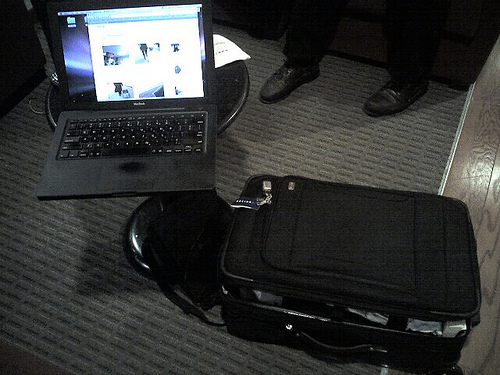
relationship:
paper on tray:
[216, 34, 245, 74] [44, 27, 251, 147]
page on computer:
[86, 8, 206, 102] [40, 3, 219, 200]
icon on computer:
[65, 12, 77, 28] [40, 3, 219, 200]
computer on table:
[40, 3, 219, 200] [211, 29, 259, 132]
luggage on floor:
[222, 167, 489, 370] [3, 21, 469, 371]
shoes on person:
[253, 56, 498, 191] [256, 3, 495, 253]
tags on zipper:
[231, 197, 261, 211] [252, 176, 276, 206]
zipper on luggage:
[257, 194, 273, 206] [147, 170, 481, 373]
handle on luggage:
[285, 326, 385, 365] [222, 167, 489, 370]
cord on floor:
[22, 92, 46, 118] [3, 21, 469, 371]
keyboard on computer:
[57, 109, 210, 161] [40, 3, 219, 200]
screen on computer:
[46, 4, 213, 109] [40, 3, 219, 200]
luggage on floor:
[222, 173, 480, 370] [3, 21, 469, 371]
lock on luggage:
[256, 177, 276, 210] [222, 173, 480, 370]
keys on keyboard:
[74, 112, 204, 152] [37, 105, 221, 195]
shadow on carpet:
[73, 134, 276, 300] [42, 31, 444, 373]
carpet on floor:
[0, 97, 454, 375] [460, 81, 499, 201]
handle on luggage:
[283, 323, 389, 365] [222, 173, 480, 370]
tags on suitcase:
[230, 177, 274, 211] [157, 148, 499, 357]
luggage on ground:
[222, 173, 480, 370] [8, 29, 485, 366]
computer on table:
[40, 3, 219, 200] [216, 49, 281, 134]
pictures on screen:
[98, 36, 190, 101] [59, 4, 204, 99]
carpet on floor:
[260, 132, 438, 164] [5, 130, 496, 365]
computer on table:
[40, 3, 219, 200] [46, 32, 253, 137]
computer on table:
[40, 18, 260, 230] [46, 32, 253, 137]